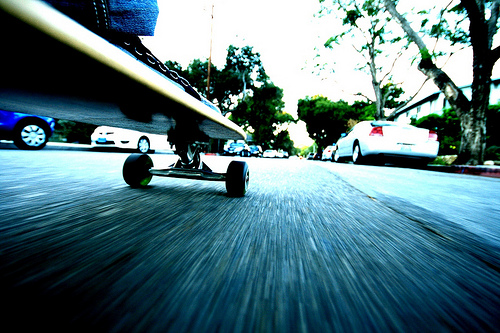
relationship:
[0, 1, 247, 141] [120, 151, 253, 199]
skateboard has wheels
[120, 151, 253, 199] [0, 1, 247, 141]
wheels attached to skateboard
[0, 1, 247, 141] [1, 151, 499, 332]
skateboard going down street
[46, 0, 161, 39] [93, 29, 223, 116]
skater has shoe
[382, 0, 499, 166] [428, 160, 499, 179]
tree standing on sidewalk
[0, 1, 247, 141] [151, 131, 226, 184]
skateboard has truck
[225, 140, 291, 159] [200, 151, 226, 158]
cars parked by sidewalk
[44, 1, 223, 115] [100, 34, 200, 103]
person has socks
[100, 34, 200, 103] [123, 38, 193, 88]
socks has circles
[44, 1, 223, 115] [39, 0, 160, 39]
skateboarder has jeans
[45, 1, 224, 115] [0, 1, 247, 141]
foot standing on skateboard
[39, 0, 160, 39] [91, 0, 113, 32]
pants have seam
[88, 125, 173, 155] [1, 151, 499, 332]
car drives on road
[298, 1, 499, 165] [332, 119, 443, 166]
trees standing by car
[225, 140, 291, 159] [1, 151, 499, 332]
cars parked on street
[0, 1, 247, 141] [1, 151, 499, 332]
skateboard rolling down street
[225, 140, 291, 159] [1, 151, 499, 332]
cars parked on road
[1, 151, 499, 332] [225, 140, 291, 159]
street has cars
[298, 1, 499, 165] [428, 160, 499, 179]
trees standing on sidewalk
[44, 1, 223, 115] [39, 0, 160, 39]
skater has jeans